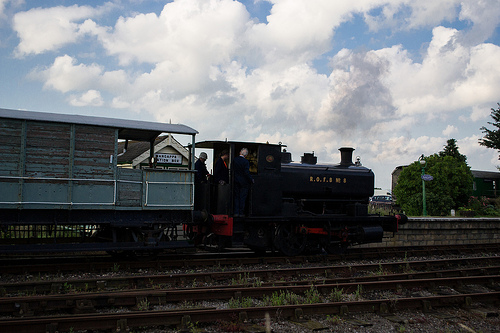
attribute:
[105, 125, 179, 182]
building — white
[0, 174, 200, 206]
railing — white